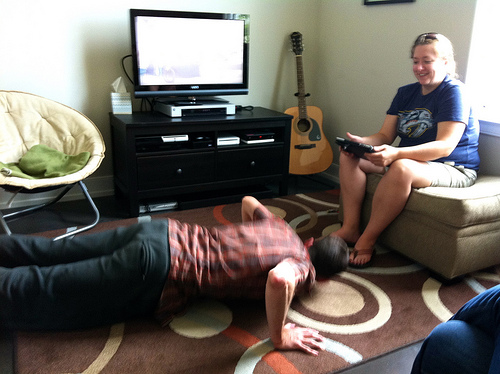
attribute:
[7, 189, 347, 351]
man — white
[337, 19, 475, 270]
woman — smiling, sitting, white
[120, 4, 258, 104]
tv — small, black, on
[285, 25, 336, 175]
guitar — brown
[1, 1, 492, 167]
wall — white, clean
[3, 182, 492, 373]
floor — brown, red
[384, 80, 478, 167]
shirt — blue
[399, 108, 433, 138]
symbol — white 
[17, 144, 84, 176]
pillow — green 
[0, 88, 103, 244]
chair — white 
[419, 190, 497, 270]
stool — tan 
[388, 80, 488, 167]
shirt — blue 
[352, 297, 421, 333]
rug — brown 